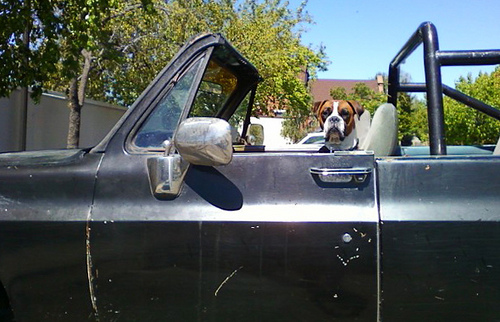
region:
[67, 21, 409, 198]
DOG SITTING IN A CAR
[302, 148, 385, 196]
CAR DOOR HANDLE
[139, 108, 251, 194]
CAR SIDE VIEW MIRROR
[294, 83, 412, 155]
DOG SITTING IN THE FRONT SEAT OF A CAR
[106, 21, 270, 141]
A CAR WINDSHIELD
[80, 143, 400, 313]
A CLOSED CAR DOOR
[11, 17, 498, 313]
A BLACK VEHICLE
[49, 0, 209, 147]
A TREE IN THE BACKGROUND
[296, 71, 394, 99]
THE ROOF OF A BUILDING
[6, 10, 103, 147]
TREES NEAR A WHITE WALL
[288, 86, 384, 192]
Large dog is sitting inside automobile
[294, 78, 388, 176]
Dog is copper colored with a white stripe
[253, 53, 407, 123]
Brown house is in the background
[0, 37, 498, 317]
automobile has a black body paint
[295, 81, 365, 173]
Dog is looking at the camera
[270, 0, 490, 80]
The sky in the background is blue and clear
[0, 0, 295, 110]
Trees in the background are green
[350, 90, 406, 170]
Automobile seats inside the car are gray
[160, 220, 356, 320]
Automobile has scratches on the side of the door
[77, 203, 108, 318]
Car door has rust in the opening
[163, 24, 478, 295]
dog sitting in black car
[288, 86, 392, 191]
brown and white dog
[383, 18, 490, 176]
black roll bars in car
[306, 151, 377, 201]
silver door handle on car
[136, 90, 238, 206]
side view mirror on door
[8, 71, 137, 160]
concrete wall behind car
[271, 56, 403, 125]
roof of house behind car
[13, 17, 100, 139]
two trees behind car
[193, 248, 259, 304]
scratch on black paint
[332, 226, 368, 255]
key slot on driver door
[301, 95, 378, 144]
A bull dog has a white and brown face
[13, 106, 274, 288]
Part of an old car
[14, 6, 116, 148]
A tree next to the wall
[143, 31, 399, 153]
The dog is sitting in the driver seat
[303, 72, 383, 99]
A building in the distance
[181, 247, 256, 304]
A scratch on the car body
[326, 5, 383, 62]
The sky is clear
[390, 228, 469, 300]
This car is black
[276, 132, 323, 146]
Another car is parked on the same block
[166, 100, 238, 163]
The right side mirror of the car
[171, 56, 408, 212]
dog sitting in driver's seat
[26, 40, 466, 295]
black truck with open back area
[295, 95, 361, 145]
droopy jowls on dog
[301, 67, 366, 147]
dog with doleful expression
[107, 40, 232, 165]
triangular window on side of windshield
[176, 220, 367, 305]
scratches on car door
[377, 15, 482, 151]
metal railing in back of truck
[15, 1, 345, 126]
trees growing by a fence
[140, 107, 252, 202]
metal casing for mirror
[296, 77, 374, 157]
brown, black and white face of staring dog